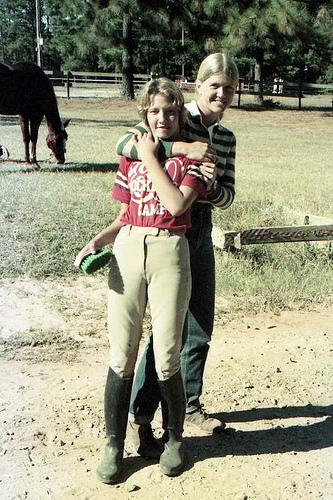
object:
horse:
[2, 52, 72, 167]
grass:
[2, 98, 331, 303]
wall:
[267, 233, 308, 245]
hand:
[128, 129, 158, 157]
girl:
[118, 51, 236, 456]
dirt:
[2, 275, 331, 497]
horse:
[0, 59, 74, 169]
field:
[227, 109, 332, 214]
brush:
[59, 246, 110, 276]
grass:
[0, 87, 330, 312]